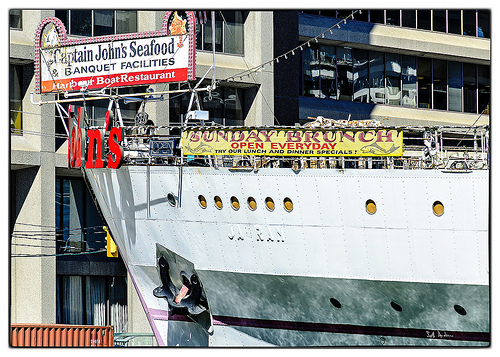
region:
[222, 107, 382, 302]
the boat is white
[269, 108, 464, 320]
the boat is white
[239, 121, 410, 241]
the boat is white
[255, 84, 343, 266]
the boat is white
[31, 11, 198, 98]
white red and blue restaurant sign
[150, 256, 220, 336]
black metal ship anchor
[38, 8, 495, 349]
large ship used as a restaurant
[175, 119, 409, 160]
yellow and red sign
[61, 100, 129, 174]
red sign on boat railing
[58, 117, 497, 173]
metal railing on boat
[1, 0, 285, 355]
white building next to a large ship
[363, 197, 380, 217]
round yellow porthole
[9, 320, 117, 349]
large orange metal storage container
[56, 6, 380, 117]
string of lights on ship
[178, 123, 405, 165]
yellow banner hanging over the railing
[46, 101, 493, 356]
front of a large ship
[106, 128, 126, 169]
large red S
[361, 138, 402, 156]
drawing of a fish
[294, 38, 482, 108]
row of dark windows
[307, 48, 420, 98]
reflection in the window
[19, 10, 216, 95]
large sign for a restaurant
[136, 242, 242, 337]
drawing on the side of the boat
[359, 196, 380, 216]
small circular window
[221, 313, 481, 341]
black strip along the side of the boat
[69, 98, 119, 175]
the letter is red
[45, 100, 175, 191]
the letter is red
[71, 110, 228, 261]
the letter is red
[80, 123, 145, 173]
the letter is red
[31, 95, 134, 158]
the letter is red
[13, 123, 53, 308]
this is a building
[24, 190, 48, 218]
the building is made of stone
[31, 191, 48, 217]
the building is grey in color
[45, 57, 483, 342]
this is a ship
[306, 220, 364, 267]
the ship is white in color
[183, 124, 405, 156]
this is a banner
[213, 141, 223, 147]
the banner is yellow in color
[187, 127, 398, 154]
these are some writings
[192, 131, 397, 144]
the writings are in bold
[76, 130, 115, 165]
the letters are red in color